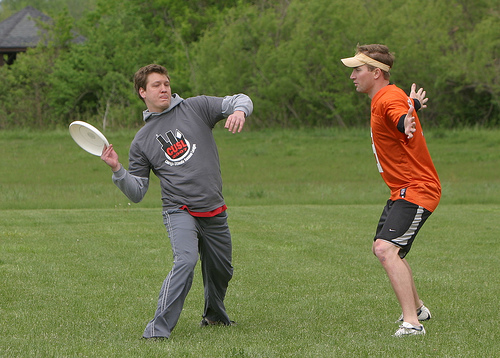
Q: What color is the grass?
A: Green.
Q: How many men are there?
A: Two.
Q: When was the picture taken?
A: Daytime.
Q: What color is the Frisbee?
A: White.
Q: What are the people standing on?
A: Grass.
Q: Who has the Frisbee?
A: The man on the left.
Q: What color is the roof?
A: Black.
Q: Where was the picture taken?
A: At a park.